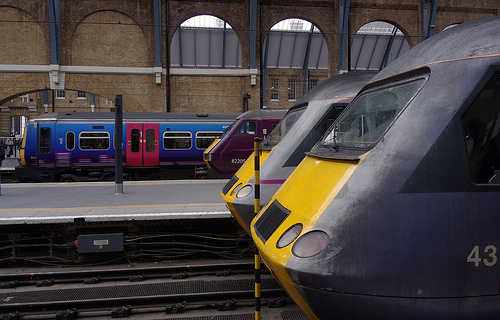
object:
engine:
[248, 19, 498, 320]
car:
[15, 113, 242, 180]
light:
[290, 229, 331, 258]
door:
[125, 121, 161, 170]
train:
[201, 106, 292, 179]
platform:
[0, 178, 236, 225]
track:
[0, 257, 285, 311]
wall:
[0, 0, 500, 115]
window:
[179, 14, 234, 31]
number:
[464, 245, 482, 269]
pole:
[252, 133, 262, 319]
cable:
[0, 240, 248, 249]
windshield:
[320, 75, 427, 149]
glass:
[162, 138, 192, 151]